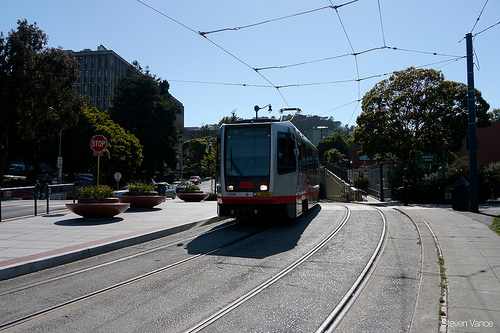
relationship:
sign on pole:
[92, 132, 106, 152] [93, 154, 100, 186]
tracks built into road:
[305, 208, 397, 318] [315, 220, 477, 323]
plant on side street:
[72, 183, 112, 201] [53, 176, 215, 225]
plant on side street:
[127, 179, 152, 194] [53, 176, 215, 225]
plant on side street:
[175, 182, 200, 194] [53, 176, 215, 225]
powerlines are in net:
[142, 1, 489, 116] [242, 33, 309, 62]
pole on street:
[441, 26, 498, 205] [438, 196, 499, 251]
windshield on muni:
[222, 125, 276, 191] [214, 112, 325, 226]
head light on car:
[258, 182, 271, 191] [216, 118, 322, 220]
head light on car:
[225, 182, 235, 192] [216, 118, 322, 220]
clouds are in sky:
[84, 8, 128, 43] [3, 0, 499, 127]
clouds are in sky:
[170, 37, 237, 74] [121, 8, 496, 124]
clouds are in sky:
[199, 100, 220, 110] [50, 5, 105, 34]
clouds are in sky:
[60, 9, 116, 47] [65, 13, 96, 38]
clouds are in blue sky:
[187, 49, 232, 75] [96, 0, 498, 123]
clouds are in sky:
[360, 22, 416, 47] [46, 4, 498, 117]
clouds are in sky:
[151, 41, 256, 118] [223, 31, 279, 76]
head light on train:
[227, 185, 234, 192] [179, 91, 351, 241]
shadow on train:
[193, 212, 299, 269] [196, 119, 325, 221]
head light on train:
[259, 184, 268, 191] [258, 183, 266, 192]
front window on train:
[227, 121, 270, 176] [207, 117, 326, 222]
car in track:
[216, 119, 319, 221] [0, 188, 460, 327]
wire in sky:
[139, 1, 494, 118] [3, 0, 499, 127]